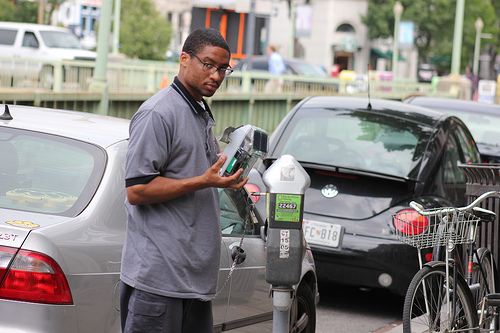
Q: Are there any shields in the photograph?
A: No, there are no shields.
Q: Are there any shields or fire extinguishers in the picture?
A: No, there are no shields or fire extinguishers.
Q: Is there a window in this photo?
A: Yes, there are windows.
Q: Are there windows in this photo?
A: Yes, there are windows.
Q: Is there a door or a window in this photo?
A: Yes, there are windows.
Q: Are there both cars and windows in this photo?
A: Yes, there are both windows and a car.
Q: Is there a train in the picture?
A: No, there are no trains.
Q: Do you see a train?
A: No, there are no trains.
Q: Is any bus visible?
A: No, there are no buses.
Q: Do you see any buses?
A: No, there are no buses.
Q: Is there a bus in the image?
A: No, there are no buses.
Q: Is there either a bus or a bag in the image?
A: No, there are no buses or bags.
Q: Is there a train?
A: No, there are no trains.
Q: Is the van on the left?
A: Yes, the van is on the left of the image.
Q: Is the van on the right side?
A: No, the van is on the left of the image.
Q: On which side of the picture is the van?
A: The van is on the left of the image.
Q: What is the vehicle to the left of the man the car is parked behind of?
A: The vehicle is a van.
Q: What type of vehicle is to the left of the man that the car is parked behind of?
A: The vehicle is a van.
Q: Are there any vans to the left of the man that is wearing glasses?
A: Yes, there is a van to the left of the man.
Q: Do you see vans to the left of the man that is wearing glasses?
A: Yes, there is a van to the left of the man.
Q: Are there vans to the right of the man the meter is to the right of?
A: No, the van is to the left of the man.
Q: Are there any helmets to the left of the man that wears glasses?
A: No, there is a van to the left of the man.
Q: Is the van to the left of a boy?
A: No, the van is to the left of the man.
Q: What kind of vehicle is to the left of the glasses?
A: The vehicle is a van.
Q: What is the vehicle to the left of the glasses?
A: The vehicle is a van.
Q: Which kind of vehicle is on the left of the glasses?
A: The vehicle is a van.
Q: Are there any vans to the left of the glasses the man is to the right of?
A: Yes, there is a van to the left of the glasses.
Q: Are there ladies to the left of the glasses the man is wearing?
A: No, there is a van to the left of the glasses.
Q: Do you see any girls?
A: No, there are no girls.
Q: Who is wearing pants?
A: The man is wearing pants.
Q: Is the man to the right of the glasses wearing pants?
A: Yes, the man is wearing pants.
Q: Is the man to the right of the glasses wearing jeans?
A: No, the man is wearing pants.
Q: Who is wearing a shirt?
A: The man is wearing a shirt.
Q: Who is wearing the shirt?
A: The man is wearing a shirt.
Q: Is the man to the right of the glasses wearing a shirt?
A: Yes, the man is wearing a shirt.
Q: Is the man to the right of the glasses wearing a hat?
A: No, the man is wearing a shirt.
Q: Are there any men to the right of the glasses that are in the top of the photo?
A: Yes, there is a man to the right of the glasses.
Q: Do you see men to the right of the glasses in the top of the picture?
A: Yes, there is a man to the right of the glasses.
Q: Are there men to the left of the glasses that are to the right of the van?
A: No, the man is to the right of the glasses.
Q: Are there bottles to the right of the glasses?
A: No, there is a man to the right of the glasses.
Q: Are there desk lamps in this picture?
A: No, there are no desk lamps.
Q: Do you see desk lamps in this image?
A: No, there are no desk lamps.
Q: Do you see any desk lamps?
A: No, there are no desk lamps.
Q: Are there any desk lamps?
A: No, there are no desk lamps.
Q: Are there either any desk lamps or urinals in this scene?
A: No, there are no desk lamps or urinals.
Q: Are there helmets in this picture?
A: No, there are no helmets.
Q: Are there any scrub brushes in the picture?
A: No, there are no scrub brushes.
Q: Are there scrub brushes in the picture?
A: No, there are no scrub brushes.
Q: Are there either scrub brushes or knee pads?
A: No, there are no scrub brushes or knee pads.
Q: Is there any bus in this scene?
A: No, there are no buses.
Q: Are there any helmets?
A: No, there are no helmets.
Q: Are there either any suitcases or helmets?
A: No, there are no helmets or suitcases.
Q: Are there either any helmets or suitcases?
A: No, there are no helmets or suitcases.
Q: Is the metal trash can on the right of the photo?
A: Yes, the trashcan is on the right of the image.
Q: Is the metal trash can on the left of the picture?
A: No, the trash bin is on the right of the image.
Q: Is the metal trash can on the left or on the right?
A: The trash can is on the right of the image.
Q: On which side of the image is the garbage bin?
A: The garbage bin is on the right of the image.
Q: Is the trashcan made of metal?
A: Yes, the trashcan is made of metal.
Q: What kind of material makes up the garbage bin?
A: The garbage bin is made of metal.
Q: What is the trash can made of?
A: The garbage bin is made of metal.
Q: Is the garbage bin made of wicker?
A: No, the garbage bin is made of metal.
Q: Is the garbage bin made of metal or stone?
A: The garbage bin is made of metal.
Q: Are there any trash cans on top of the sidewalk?
A: Yes, there is a trash can on top of the sidewalk.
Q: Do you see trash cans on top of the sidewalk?
A: Yes, there is a trash can on top of the sidewalk.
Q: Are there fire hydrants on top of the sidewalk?
A: No, there is a trash can on top of the sidewalk.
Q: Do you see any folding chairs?
A: No, there are no folding chairs.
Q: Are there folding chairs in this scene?
A: No, there are no folding chairs.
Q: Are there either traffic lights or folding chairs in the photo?
A: No, there are no folding chairs or traffic lights.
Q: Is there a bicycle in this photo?
A: Yes, there is a bicycle.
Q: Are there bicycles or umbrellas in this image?
A: Yes, there is a bicycle.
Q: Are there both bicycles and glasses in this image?
A: Yes, there are both a bicycle and glasses.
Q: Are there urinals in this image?
A: No, there are no urinals.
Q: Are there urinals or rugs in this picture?
A: No, there are no urinals or rugs.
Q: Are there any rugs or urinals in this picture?
A: No, there are no urinals or rugs.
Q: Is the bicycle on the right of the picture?
A: Yes, the bicycle is on the right of the image.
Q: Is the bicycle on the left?
A: No, the bicycle is on the right of the image.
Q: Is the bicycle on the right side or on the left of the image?
A: The bicycle is on the right of the image.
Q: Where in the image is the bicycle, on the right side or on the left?
A: The bicycle is on the right of the image.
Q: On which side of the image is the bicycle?
A: The bicycle is on the right of the image.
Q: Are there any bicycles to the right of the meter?
A: Yes, there is a bicycle to the right of the meter.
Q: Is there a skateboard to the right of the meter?
A: No, there is a bicycle to the right of the meter.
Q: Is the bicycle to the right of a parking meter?
A: Yes, the bicycle is to the right of a parking meter.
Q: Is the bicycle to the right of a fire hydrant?
A: No, the bicycle is to the right of a parking meter.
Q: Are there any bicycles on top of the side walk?
A: Yes, there is a bicycle on top of the side walk.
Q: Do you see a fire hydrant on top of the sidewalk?
A: No, there is a bicycle on top of the sidewalk.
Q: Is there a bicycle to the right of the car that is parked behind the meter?
A: Yes, there is a bicycle to the right of the car.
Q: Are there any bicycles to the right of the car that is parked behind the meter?
A: Yes, there is a bicycle to the right of the car.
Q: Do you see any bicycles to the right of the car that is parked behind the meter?
A: Yes, there is a bicycle to the right of the car.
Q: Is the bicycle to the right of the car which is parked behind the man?
A: Yes, the bicycle is to the right of the car.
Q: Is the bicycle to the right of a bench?
A: No, the bicycle is to the right of the car.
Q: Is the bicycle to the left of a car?
A: No, the bicycle is to the right of a car.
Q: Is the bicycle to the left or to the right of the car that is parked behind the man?
A: The bicycle is to the right of the car.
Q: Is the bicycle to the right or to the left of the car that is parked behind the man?
A: The bicycle is to the right of the car.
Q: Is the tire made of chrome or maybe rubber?
A: The tire is made of rubber.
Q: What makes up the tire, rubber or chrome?
A: The tire is made of rubber.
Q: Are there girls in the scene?
A: No, there are no girls.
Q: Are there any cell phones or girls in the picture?
A: No, there are no girls or cell phones.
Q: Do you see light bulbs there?
A: No, there are no light bulbs.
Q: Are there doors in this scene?
A: Yes, there is a door.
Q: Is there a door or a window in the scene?
A: Yes, there is a door.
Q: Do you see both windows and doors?
A: Yes, there are both a door and a window.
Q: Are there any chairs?
A: No, there are no chairs.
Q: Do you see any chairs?
A: No, there are no chairs.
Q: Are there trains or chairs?
A: No, there are no chairs or trains.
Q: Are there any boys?
A: No, there are no boys.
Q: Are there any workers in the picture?
A: No, there are no workers.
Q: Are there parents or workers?
A: No, there are no workers or parents.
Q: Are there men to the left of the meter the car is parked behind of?
A: Yes, there is a man to the left of the meter.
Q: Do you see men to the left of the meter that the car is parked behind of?
A: Yes, there is a man to the left of the meter.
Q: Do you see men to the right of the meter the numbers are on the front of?
A: No, the man is to the left of the meter.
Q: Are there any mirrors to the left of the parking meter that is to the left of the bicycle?
A: No, there is a man to the left of the parking meter.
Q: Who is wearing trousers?
A: The man is wearing trousers.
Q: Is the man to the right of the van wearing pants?
A: Yes, the man is wearing pants.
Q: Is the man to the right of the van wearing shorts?
A: No, the man is wearing pants.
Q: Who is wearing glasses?
A: The man is wearing glasses.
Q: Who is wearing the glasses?
A: The man is wearing glasses.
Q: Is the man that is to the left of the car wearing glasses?
A: Yes, the man is wearing glasses.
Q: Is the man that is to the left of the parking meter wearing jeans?
A: No, the man is wearing glasses.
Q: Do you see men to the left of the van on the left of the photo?
A: No, the man is to the right of the van.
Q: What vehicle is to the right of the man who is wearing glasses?
A: The vehicle is a car.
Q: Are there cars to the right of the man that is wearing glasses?
A: Yes, there is a car to the right of the man.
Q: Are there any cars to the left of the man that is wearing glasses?
A: No, the car is to the right of the man.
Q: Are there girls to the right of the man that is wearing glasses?
A: No, there is a car to the right of the man.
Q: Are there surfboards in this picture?
A: No, there are no surfboards.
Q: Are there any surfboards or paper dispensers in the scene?
A: No, there are no surfboards or paper dispensers.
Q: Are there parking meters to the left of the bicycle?
A: Yes, there is a parking meter to the left of the bicycle.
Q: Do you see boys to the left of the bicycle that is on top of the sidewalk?
A: No, there is a parking meter to the left of the bicycle.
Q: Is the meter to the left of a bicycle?
A: Yes, the meter is to the left of a bicycle.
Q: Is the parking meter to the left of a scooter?
A: No, the parking meter is to the left of a bicycle.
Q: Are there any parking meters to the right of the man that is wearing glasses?
A: Yes, there is a parking meter to the right of the man.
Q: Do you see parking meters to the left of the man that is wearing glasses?
A: No, the parking meter is to the right of the man.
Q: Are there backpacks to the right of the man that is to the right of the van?
A: No, there is a parking meter to the right of the man.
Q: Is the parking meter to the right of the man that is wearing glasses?
A: Yes, the parking meter is to the right of the man.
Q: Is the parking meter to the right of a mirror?
A: No, the parking meter is to the right of the man.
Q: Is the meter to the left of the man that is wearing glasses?
A: No, the meter is to the right of the man.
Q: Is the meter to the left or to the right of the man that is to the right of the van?
A: The meter is to the right of the man.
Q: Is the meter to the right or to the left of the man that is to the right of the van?
A: The meter is to the right of the man.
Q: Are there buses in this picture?
A: No, there are no buses.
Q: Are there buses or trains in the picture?
A: No, there are no buses or trains.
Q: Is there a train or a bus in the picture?
A: No, there are no buses or trains.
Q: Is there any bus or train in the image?
A: No, there are no buses or trains.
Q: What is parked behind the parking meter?
A: The car is parked behind the parking meter.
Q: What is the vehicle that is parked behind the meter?
A: The vehicle is a car.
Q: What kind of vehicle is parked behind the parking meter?
A: The vehicle is a car.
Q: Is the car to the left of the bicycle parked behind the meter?
A: Yes, the car is parked behind the meter.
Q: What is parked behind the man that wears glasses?
A: The car is parked behind the man.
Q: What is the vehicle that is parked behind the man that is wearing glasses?
A: The vehicle is a car.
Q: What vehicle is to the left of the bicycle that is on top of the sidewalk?
A: The vehicle is a car.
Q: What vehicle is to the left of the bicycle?
A: The vehicle is a car.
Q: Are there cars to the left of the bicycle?
A: Yes, there is a car to the left of the bicycle.